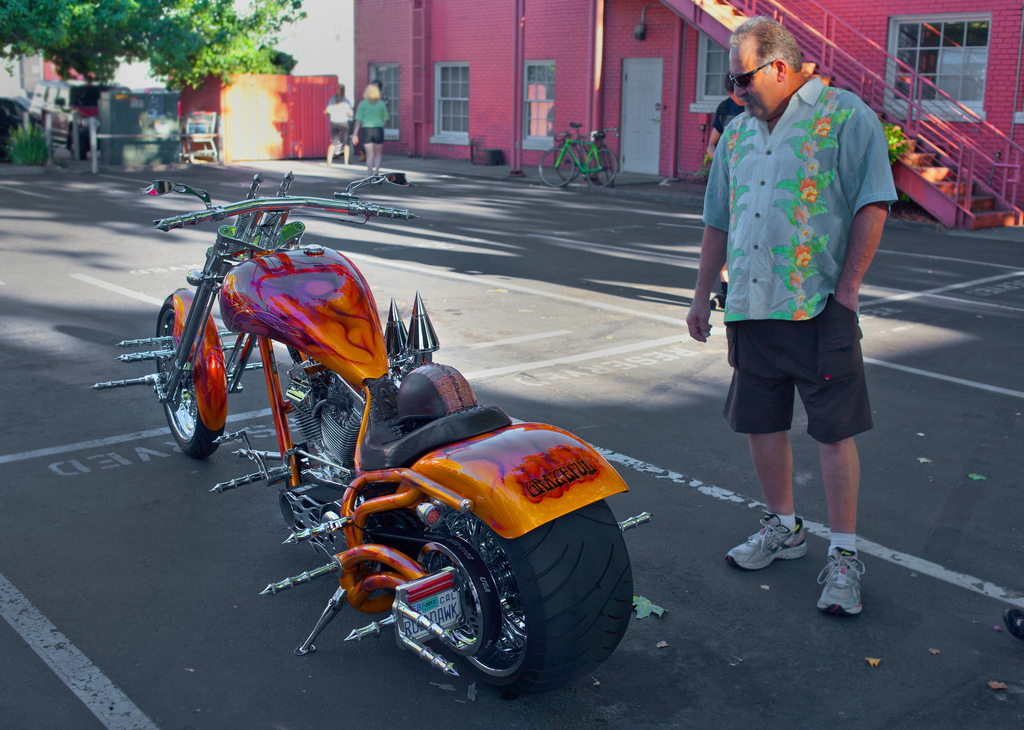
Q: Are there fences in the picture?
A: No, there are no fences.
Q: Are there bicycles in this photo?
A: Yes, there is a bicycle.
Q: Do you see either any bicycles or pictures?
A: Yes, there is a bicycle.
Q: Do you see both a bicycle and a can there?
A: No, there is a bicycle but no cans.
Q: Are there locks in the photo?
A: No, there are no locks.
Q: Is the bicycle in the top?
A: Yes, the bicycle is in the top of the image.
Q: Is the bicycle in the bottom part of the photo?
A: No, the bicycle is in the top of the image.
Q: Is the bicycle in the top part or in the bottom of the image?
A: The bicycle is in the top of the image.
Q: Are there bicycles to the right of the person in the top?
A: Yes, there is a bicycle to the right of the person.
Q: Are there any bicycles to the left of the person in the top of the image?
A: No, the bicycle is to the right of the person.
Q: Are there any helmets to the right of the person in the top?
A: No, there is a bicycle to the right of the person.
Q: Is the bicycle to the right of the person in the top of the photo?
A: Yes, the bicycle is to the right of the person.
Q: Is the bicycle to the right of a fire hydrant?
A: No, the bicycle is to the right of the person.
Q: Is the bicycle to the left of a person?
A: No, the bicycle is to the right of a person.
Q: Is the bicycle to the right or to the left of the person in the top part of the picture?
A: The bicycle is to the right of the person.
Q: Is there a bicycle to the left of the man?
A: Yes, there is a bicycle to the left of the man.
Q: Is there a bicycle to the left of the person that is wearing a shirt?
A: Yes, there is a bicycle to the left of the man.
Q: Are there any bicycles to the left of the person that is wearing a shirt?
A: Yes, there is a bicycle to the left of the man.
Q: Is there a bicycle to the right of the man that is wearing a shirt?
A: No, the bicycle is to the left of the man.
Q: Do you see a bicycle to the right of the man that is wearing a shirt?
A: No, the bicycle is to the left of the man.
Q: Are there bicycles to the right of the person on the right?
A: No, the bicycle is to the left of the man.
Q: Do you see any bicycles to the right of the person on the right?
A: No, the bicycle is to the left of the man.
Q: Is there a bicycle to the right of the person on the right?
A: No, the bicycle is to the left of the man.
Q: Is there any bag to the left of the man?
A: No, there is a bicycle to the left of the man.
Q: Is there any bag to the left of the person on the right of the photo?
A: No, there is a bicycle to the left of the man.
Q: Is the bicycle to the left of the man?
A: Yes, the bicycle is to the left of the man.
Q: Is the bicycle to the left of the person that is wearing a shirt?
A: Yes, the bicycle is to the left of the man.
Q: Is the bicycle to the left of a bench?
A: No, the bicycle is to the left of the man.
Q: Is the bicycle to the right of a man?
A: No, the bicycle is to the left of a man.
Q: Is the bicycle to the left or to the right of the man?
A: The bicycle is to the left of the man.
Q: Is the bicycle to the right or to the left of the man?
A: The bicycle is to the left of the man.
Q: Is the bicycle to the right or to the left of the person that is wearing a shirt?
A: The bicycle is to the left of the man.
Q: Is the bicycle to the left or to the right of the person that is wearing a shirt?
A: The bicycle is to the left of the man.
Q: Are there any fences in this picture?
A: No, there are no fences.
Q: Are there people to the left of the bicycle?
A: Yes, there is a person to the left of the bicycle.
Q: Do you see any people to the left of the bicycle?
A: Yes, there is a person to the left of the bicycle.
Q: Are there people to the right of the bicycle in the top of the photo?
A: No, the person is to the left of the bicycle.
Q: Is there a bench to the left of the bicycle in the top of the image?
A: No, there is a person to the left of the bicycle.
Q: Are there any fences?
A: No, there are no fences.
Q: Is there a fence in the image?
A: No, there are no fences.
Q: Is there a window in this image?
A: Yes, there is a window.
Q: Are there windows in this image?
A: Yes, there is a window.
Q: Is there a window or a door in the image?
A: Yes, there is a window.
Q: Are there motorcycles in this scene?
A: Yes, there is a motorcycle.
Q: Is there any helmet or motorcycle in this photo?
A: Yes, there is a motorcycle.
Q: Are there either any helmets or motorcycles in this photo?
A: Yes, there is a motorcycle.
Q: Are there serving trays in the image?
A: No, there are no serving trays.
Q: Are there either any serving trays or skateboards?
A: No, there are no serving trays or skateboards.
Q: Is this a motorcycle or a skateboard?
A: This is a motorcycle.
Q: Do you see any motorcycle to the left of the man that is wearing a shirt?
A: Yes, there is a motorcycle to the left of the man.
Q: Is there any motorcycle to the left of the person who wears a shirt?
A: Yes, there is a motorcycle to the left of the man.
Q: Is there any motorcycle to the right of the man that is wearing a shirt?
A: No, the motorcycle is to the left of the man.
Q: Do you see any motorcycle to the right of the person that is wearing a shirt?
A: No, the motorcycle is to the left of the man.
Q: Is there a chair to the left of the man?
A: No, there is a motorcycle to the left of the man.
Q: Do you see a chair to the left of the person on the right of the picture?
A: No, there is a motorcycle to the left of the man.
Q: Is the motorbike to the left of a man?
A: Yes, the motorbike is to the left of a man.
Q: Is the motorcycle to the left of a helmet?
A: No, the motorcycle is to the left of a man.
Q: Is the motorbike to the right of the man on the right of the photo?
A: No, the motorbike is to the left of the man.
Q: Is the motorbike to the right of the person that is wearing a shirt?
A: No, the motorbike is to the left of the man.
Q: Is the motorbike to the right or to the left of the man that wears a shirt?
A: The motorbike is to the left of the man.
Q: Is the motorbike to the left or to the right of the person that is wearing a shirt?
A: The motorbike is to the left of the man.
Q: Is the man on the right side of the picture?
A: Yes, the man is on the right of the image.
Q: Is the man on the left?
A: No, the man is on the right of the image.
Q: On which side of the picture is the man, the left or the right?
A: The man is on the right of the image.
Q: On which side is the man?
A: The man is on the right of the image.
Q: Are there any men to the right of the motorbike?
A: Yes, there is a man to the right of the motorbike.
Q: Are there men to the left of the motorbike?
A: No, the man is to the right of the motorbike.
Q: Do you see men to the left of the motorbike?
A: No, the man is to the right of the motorbike.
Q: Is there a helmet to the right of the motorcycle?
A: No, there is a man to the right of the motorcycle.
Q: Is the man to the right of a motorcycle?
A: Yes, the man is to the right of a motorcycle.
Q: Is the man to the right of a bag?
A: No, the man is to the right of a motorcycle.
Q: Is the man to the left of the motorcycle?
A: No, the man is to the right of the motorcycle.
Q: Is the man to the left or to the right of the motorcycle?
A: The man is to the right of the motorcycle.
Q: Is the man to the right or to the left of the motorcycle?
A: The man is to the right of the motorcycle.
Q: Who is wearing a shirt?
A: The man is wearing a shirt.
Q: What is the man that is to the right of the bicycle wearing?
A: The man is wearing a shirt.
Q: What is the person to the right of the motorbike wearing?
A: The man is wearing a shirt.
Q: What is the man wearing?
A: The man is wearing a shirt.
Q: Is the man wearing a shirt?
A: Yes, the man is wearing a shirt.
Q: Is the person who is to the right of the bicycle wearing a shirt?
A: Yes, the man is wearing a shirt.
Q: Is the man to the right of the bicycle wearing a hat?
A: No, the man is wearing a shirt.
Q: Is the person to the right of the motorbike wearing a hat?
A: No, the man is wearing a shirt.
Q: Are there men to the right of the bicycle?
A: Yes, there is a man to the right of the bicycle.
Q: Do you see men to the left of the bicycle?
A: No, the man is to the right of the bicycle.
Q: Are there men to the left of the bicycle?
A: No, the man is to the right of the bicycle.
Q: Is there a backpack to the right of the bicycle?
A: No, there is a man to the right of the bicycle.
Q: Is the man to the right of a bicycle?
A: Yes, the man is to the right of a bicycle.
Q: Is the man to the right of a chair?
A: No, the man is to the right of a bicycle.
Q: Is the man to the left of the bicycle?
A: No, the man is to the right of the bicycle.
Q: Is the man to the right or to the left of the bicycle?
A: The man is to the right of the bicycle.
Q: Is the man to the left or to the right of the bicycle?
A: The man is to the right of the bicycle.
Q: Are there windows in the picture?
A: Yes, there is a window.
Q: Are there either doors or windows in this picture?
A: Yes, there is a window.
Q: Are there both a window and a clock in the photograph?
A: No, there is a window but no clocks.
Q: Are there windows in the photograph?
A: Yes, there is a window.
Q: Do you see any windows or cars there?
A: Yes, there is a window.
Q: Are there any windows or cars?
A: Yes, there is a window.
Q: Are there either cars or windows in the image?
A: Yes, there is a window.